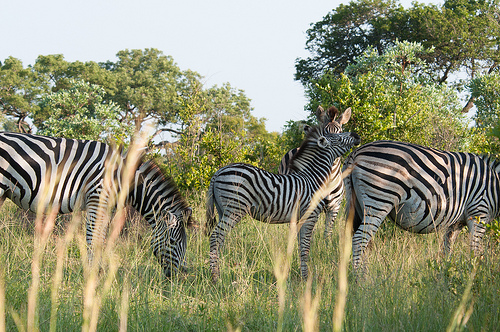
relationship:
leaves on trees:
[0, 1, 499, 210] [2, 0, 499, 220]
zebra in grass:
[340, 132, 482, 274] [6, 190, 484, 325]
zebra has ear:
[340, 138, 498, 271] [315, 134, 329, 146]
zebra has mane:
[340, 138, 498, 271] [289, 124, 331, 170]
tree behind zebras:
[5, 42, 273, 197] [4, 104, 484, 282]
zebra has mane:
[3, 127, 194, 287] [121, 145, 193, 229]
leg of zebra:
[294, 209, 321, 272] [204, 125, 350, 275]